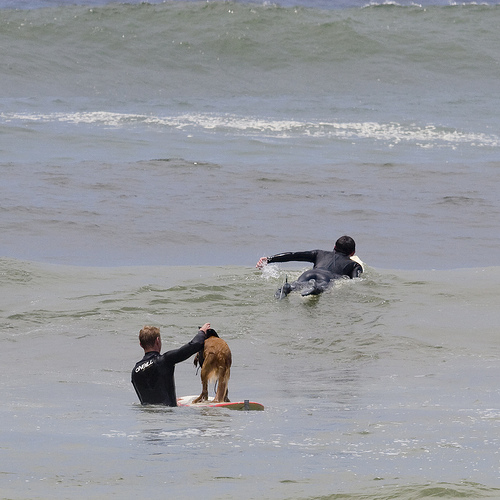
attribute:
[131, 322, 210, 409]
man — white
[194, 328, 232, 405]
dog — brown, small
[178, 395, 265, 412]
surfboard — red, white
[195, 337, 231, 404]
fur — brown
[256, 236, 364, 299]
man — young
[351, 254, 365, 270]
surfboard — white tip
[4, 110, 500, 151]
wave — small, coming from afar, about to break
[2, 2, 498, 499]
ocean — vast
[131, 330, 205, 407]
wet suit — black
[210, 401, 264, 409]
stripe — red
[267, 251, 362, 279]
shirt — black, wet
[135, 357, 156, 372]
name of brand — written in white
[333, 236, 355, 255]
hair — black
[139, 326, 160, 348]
hair — reddish-blonde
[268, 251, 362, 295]
wet suit — black